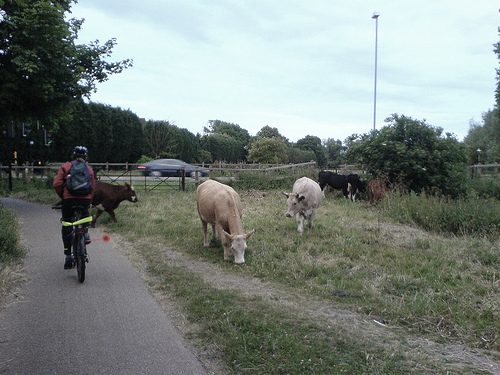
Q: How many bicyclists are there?
A: 1.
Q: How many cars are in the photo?
A: 1.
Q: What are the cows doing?
A: Grazing.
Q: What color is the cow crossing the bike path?
A: Brown.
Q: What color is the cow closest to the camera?
A: Tan.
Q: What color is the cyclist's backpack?
A: Blue.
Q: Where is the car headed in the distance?
A: Right.